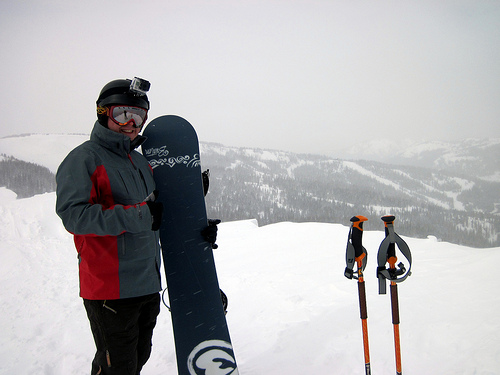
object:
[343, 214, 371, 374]
hooker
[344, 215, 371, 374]
pole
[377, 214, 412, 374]
pole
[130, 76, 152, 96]
camera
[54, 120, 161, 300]
coat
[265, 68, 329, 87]
cloud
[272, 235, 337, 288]
snow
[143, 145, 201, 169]
sign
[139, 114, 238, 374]
board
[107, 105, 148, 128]
goggles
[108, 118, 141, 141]
face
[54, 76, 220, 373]
person